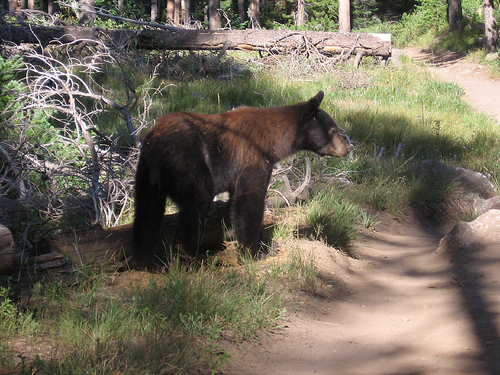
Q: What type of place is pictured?
A: It is a field.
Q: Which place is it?
A: It is a field.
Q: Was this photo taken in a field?
A: Yes, it was taken in a field.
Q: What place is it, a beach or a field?
A: It is a field.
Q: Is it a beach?
A: No, it is a field.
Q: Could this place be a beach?
A: No, it is a field.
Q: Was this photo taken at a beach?
A: No, the picture was taken in a field.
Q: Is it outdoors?
A: Yes, it is outdoors.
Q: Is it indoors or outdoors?
A: It is outdoors.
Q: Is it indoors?
A: No, it is outdoors.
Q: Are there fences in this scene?
A: No, there are no fences.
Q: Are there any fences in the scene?
A: No, there are no fences.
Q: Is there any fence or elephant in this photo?
A: No, there are no fences or elephants.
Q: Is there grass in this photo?
A: Yes, there is grass.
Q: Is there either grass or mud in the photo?
A: Yes, there is grass.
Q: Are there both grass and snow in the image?
A: No, there is grass but no snow.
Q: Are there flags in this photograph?
A: No, there are no flags.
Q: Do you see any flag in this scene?
A: No, there are no flags.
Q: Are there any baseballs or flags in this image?
A: No, there are no flags or baseballs.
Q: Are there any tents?
A: No, there are no tents.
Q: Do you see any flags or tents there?
A: No, there are no tents or flags.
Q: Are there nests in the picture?
A: No, there are no nests.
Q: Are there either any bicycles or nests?
A: No, there are no nests or bicycles.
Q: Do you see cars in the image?
A: No, there are no cars.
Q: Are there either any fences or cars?
A: No, there are no cars or fences.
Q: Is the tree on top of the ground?
A: Yes, the tree is on top of the ground.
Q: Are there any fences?
A: No, there are no fences.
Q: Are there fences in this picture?
A: No, there are no fences.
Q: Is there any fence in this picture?
A: No, there are no fences.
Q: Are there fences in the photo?
A: No, there are no fences.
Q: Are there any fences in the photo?
A: No, there are no fences.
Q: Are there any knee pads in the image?
A: No, there are no knee pads.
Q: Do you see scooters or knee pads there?
A: No, there are no knee pads or scooters.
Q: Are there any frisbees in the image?
A: No, there are no frisbees.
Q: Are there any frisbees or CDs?
A: No, there are no frisbees or cds.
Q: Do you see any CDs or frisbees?
A: No, there are no frisbees or cds.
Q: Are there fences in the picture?
A: No, there are no fences.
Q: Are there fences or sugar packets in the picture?
A: No, there are no fences or sugar packets.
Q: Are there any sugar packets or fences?
A: No, there are no fences or sugar packets.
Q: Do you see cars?
A: No, there are no cars.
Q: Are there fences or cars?
A: No, there are no cars or fences.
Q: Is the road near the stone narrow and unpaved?
A: Yes, the road is narrow and unpaved.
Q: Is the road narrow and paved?
A: No, the road is narrow but unpaved.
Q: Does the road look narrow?
A: Yes, the road is narrow.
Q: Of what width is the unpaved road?
A: The road is narrow.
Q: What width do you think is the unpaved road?
A: The road is narrow.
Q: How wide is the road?
A: The road is narrow.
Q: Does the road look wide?
A: No, the road is narrow.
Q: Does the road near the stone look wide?
A: No, the road is narrow.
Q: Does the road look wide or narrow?
A: The road is narrow.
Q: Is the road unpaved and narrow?
A: Yes, the road is unpaved and narrow.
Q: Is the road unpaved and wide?
A: No, the road is unpaved but narrow.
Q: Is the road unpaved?
A: Yes, the road is unpaved.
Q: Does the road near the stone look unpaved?
A: Yes, the road is unpaved.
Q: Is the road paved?
A: No, the road is unpaved.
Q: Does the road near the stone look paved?
A: No, the road is unpaved.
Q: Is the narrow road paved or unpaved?
A: The road is unpaved.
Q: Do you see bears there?
A: Yes, there is a bear.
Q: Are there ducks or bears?
A: Yes, there is a bear.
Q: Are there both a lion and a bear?
A: No, there is a bear but no lions.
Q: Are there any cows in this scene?
A: No, there are no cows.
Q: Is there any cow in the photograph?
A: No, there are no cows.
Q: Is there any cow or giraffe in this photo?
A: No, there are no cows or giraffes.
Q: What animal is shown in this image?
A: The animal is a bear.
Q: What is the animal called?
A: The animal is a bear.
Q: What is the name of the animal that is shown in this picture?
A: The animal is a bear.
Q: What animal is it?
A: The animal is a bear.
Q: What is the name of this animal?
A: This is a bear.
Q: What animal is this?
A: This is a bear.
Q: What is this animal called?
A: This is a bear.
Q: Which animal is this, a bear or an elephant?
A: This is a bear.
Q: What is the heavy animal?
A: The animal is a bear.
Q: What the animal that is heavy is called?
A: The animal is a bear.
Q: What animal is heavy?
A: The animal is a bear.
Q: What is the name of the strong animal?
A: The animal is a bear.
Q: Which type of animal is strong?
A: The animal is a bear.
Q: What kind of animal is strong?
A: The animal is a bear.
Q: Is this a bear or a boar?
A: This is a bear.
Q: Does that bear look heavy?
A: Yes, the bear is heavy.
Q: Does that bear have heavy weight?
A: Yes, the bear is heavy.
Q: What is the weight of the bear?
A: The bear is heavy.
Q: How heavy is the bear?
A: The bear is heavy.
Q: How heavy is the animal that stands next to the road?
A: The bear is heavy.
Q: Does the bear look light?
A: No, the bear is heavy.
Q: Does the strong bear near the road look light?
A: No, the bear is heavy.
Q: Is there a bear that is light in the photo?
A: No, there is a bear but it is heavy.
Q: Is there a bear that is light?
A: No, there is a bear but it is heavy.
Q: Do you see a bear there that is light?
A: No, there is a bear but it is heavy.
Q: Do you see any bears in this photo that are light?
A: No, there is a bear but it is heavy.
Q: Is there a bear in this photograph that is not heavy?
A: No, there is a bear but it is heavy.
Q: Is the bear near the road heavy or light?
A: The bear is heavy.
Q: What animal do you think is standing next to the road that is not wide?
A: The bear is standing next to the road.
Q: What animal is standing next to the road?
A: The bear is standing next to the road.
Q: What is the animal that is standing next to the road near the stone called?
A: The animal is a bear.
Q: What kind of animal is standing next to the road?
A: The animal is a bear.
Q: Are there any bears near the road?
A: Yes, there is a bear near the road.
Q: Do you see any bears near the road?
A: Yes, there is a bear near the road.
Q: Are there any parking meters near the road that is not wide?
A: No, there is a bear near the road.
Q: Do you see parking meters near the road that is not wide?
A: No, there is a bear near the road.